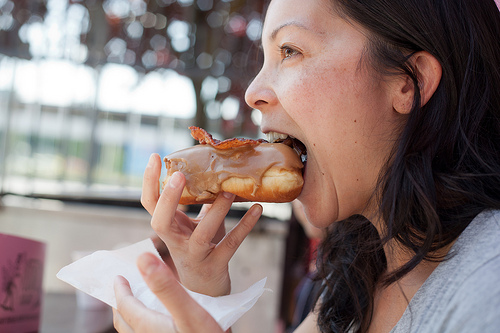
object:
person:
[112, 0, 500, 333]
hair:
[302, 0, 500, 333]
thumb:
[134, 250, 211, 330]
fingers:
[138, 154, 161, 212]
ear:
[393, 51, 443, 114]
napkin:
[56, 238, 268, 333]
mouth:
[258, 126, 310, 189]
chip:
[187, 126, 259, 149]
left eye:
[278, 45, 306, 61]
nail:
[168, 170, 183, 189]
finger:
[148, 170, 189, 235]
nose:
[242, 56, 277, 110]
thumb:
[113, 275, 174, 331]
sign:
[0, 230, 43, 333]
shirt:
[388, 209, 499, 333]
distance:
[0, 0, 322, 333]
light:
[167, 19, 190, 51]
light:
[105, 37, 126, 56]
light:
[66, 3, 87, 23]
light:
[227, 12, 247, 33]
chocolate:
[163, 139, 304, 206]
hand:
[103, 252, 225, 333]